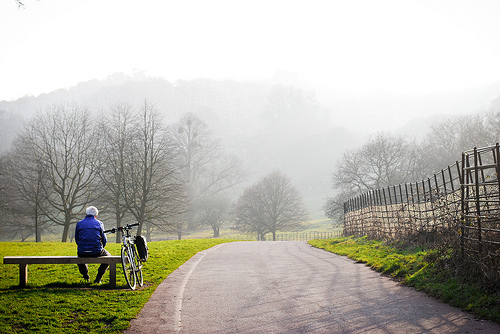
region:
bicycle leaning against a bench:
[108, 212, 150, 298]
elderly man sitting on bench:
[5, 193, 119, 290]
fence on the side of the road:
[336, 136, 496, 275]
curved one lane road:
[125, 212, 461, 332]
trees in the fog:
[174, 116, 322, 247]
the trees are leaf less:
[122, 113, 296, 243]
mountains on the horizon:
[8, 62, 385, 156]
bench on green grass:
[8, 239, 65, 321]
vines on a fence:
[434, 181, 493, 286]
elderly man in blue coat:
[74, 195, 114, 292]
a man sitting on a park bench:
[3, 206, 110, 288]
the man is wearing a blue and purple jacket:
[73, 216, 106, 253]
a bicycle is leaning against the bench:
[102, 219, 149, 287]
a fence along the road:
[343, 143, 498, 255]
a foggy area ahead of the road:
[1, 1, 499, 201]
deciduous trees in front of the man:
[1, 96, 183, 206]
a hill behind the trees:
[1, 75, 345, 203]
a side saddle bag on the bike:
[133, 234, 150, 261]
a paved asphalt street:
[148, 240, 498, 332]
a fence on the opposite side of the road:
[244, 220, 343, 242]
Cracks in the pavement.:
[314, 288, 341, 323]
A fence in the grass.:
[339, 193, 498, 256]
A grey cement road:
[201, 242, 309, 332]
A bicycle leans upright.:
[110, 222, 158, 289]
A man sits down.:
[70, 199, 112, 287]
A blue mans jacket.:
[74, 215, 106, 253]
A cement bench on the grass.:
[3, 253, 130, 293]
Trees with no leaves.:
[1, 111, 81, 244]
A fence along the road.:
[249, 231, 343, 241]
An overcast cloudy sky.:
[231, 76, 396, 133]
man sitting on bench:
[73, 204, 115, 286]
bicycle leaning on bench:
[105, 224, 157, 292]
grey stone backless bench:
[3, 251, 135, 285]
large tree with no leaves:
[232, 167, 308, 246]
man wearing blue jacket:
[76, 204, 112, 281]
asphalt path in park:
[131, 236, 491, 332]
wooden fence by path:
[337, 139, 499, 260]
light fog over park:
[3, 76, 495, 235]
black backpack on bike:
[131, 231, 152, 263]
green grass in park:
[1, 233, 254, 333]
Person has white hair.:
[76, 195, 103, 223]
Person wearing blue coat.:
[62, 207, 106, 263]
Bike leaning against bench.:
[99, 210, 190, 331]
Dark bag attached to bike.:
[123, 217, 184, 297]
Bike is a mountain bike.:
[98, 213, 185, 330]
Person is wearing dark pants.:
[38, 242, 158, 292]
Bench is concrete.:
[12, 245, 117, 282]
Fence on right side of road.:
[373, 177, 494, 202]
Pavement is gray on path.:
[230, 245, 336, 330]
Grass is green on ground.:
[49, 286, 106, 332]